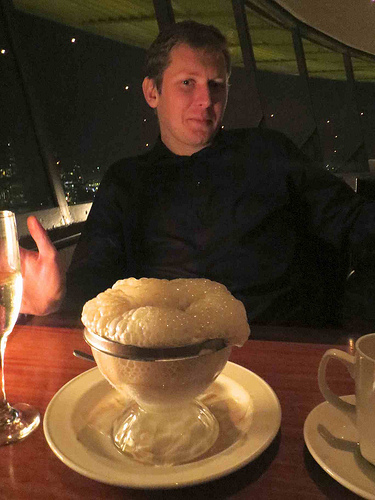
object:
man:
[61, 16, 373, 327]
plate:
[304, 387, 374, 499]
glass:
[0, 209, 44, 446]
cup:
[314, 332, 374, 463]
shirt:
[59, 123, 372, 327]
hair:
[140, 19, 231, 92]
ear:
[140, 73, 158, 107]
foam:
[75, 274, 250, 357]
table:
[2, 307, 371, 496]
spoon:
[71, 347, 92, 367]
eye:
[181, 77, 197, 88]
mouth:
[187, 114, 216, 128]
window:
[2, 1, 374, 229]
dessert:
[76, 270, 252, 466]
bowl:
[77, 327, 240, 462]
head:
[138, 17, 236, 150]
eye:
[205, 79, 223, 93]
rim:
[84, 317, 253, 362]